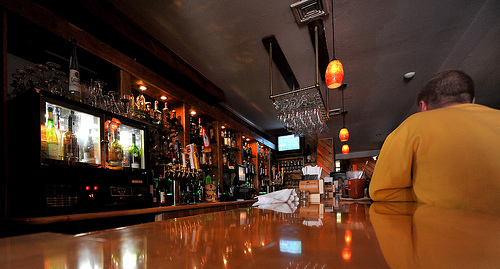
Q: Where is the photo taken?
A: In a bar.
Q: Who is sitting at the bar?
A: A man.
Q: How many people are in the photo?
A: One.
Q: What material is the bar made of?
A: Wood.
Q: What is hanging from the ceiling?
A: Glasses.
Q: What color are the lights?
A: Orange.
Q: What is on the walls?
A: Glasses and bottles.